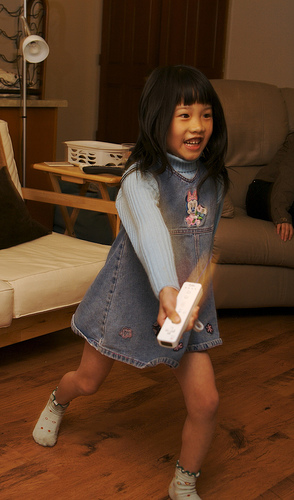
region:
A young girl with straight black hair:
[120, 62, 242, 183]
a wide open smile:
[181, 134, 212, 157]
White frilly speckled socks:
[24, 379, 69, 460]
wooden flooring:
[73, 419, 139, 487]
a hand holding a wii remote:
[142, 267, 214, 360]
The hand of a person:
[271, 213, 291, 249]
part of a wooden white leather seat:
[32, 178, 75, 352]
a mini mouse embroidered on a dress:
[183, 190, 209, 233]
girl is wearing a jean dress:
[63, 252, 139, 364]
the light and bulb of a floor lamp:
[16, 26, 58, 73]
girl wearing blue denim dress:
[32, 56, 263, 499]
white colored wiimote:
[157, 281, 208, 347]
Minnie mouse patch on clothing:
[181, 188, 207, 228]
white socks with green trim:
[32, 386, 73, 446]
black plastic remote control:
[80, 164, 124, 177]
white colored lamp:
[19, 14, 49, 189]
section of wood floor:
[81, 421, 160, 498]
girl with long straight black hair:
[125, 64, 228, 187]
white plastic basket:
[64, 139, 127, 169]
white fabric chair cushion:
[1, 230, 121, 318]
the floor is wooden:
[93, 472, 106, 487]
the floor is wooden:
[116, 470, 130, 488]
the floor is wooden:
[116, 476, 123, 486]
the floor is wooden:
[113, 475, 118, 485]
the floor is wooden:
[104, 467, 114, 482]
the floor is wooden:
[117, 477, 129, 490]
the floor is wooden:
[120, 466, 131, 485]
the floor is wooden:
[109, 484, 121, 496]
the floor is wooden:
[86, 492, 93, 497]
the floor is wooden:
[89, 478, 99, 490]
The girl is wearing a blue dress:
[87, 79, 236, 363]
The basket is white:
[59, 127, 129, 169]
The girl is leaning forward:
[88, 62, 225, 447]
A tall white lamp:
[9, 29, 48, 191]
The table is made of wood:
[31, 148, 133, 233]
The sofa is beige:
[185, 74, 286, 305]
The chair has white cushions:
[4, 129, 108, 305]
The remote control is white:
[158, 260, 209, 367]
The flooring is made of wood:
[49, 347, 274, 481]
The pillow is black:
[3, 166, 55, 256]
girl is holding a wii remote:
[144, 279, 226, 369]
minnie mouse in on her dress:
[177, 186, 221, 237]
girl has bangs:
[161, 77, 234, 119]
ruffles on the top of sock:
[159, 460, 213, 492]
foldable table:
[36, 163, 131, 239]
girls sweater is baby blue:
[118, 197, 191, 286]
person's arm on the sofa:
[261, 138, 290, 241]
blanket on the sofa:
[0, 129, 63, 247]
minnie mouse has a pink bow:
[176, 190, 204, 206]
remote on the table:
[82, 159, 137, 182]